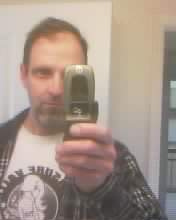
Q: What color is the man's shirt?
A: White.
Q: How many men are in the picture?
A: One.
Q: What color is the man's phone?
A: Silver.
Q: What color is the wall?
A: Beige.